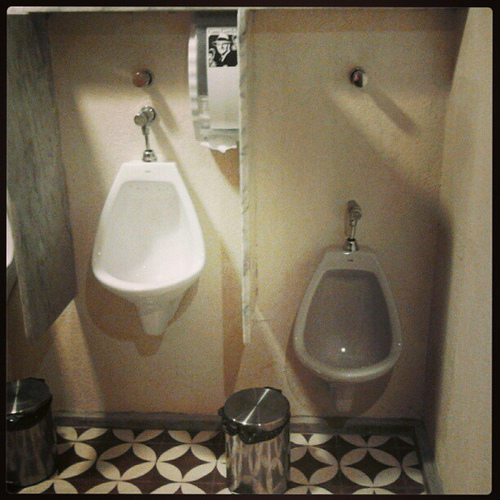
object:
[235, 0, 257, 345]
stall wall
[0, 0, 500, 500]
bathroom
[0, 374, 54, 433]
bag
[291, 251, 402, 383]
urinal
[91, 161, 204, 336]
urinal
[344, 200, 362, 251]
pipe